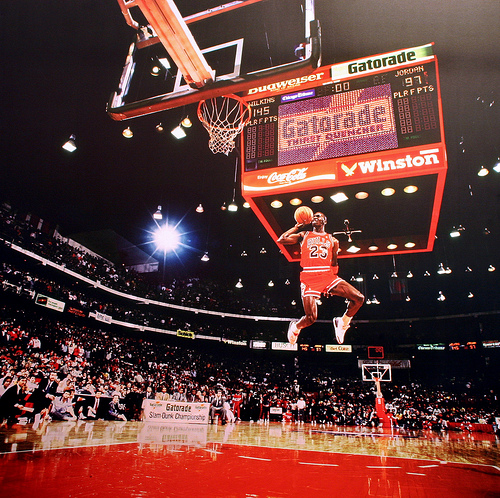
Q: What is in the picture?
A: A basketball court.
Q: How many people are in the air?
A: One.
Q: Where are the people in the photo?
A: Basketball game.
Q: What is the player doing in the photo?
A: Basketball jump shot.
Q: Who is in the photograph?
A: A basketball player.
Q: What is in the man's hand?
A: A basketball.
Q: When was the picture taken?
A: Nighttime.